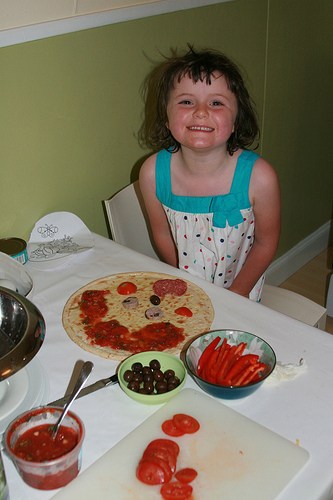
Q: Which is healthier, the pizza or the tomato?
A: The tomato is healthier than the pizza.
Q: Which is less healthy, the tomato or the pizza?
A: The pizza is less healthy than the tomato.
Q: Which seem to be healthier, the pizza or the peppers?
A: The peppers are healthier than the pizza.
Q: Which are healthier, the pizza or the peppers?
A: The peppers are healthier than the pizza.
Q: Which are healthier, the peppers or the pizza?
A: The peppers are healthier than the pizza.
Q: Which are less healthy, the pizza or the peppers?
A: The pizza are less healthy than the peppers.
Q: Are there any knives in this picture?
A: Yes, there is a knife.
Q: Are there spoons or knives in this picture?
A: Yes, there is a knife.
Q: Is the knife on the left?
A: Yes, the knife is on the left of the image.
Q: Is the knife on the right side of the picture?
A: No, the knife is on the left of the image.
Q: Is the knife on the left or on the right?
A: The knife is on the left of the image.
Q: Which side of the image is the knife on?
A: The knife is on the left of the image.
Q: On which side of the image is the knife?
A: The knife is on the left of the image.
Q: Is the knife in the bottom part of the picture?
A: Yes, the knife is in the bottom of the image.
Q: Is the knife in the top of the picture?
A: No, the knife is in the bottom of the image.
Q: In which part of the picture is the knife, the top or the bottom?
A: The knife is in the bottom of the image.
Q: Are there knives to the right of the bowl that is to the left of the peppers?
A: No, the knife is to the left of the bowl.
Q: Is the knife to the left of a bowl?
A: Yes, the knife is to the left of a bowl.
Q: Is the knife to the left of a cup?
A: No, the knife is to the left of a bowl.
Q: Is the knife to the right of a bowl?
A: No, the knife is to the left of a bowl.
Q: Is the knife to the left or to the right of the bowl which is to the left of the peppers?
A: The knife is to the left of the bowl.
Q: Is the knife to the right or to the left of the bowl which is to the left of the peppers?
A: The knife is to the left of the bowl.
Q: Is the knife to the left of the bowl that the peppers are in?
A: Yes, the knife is to the left of the bowl.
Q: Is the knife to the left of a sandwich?
A: No, the knife is to the left of the bowl.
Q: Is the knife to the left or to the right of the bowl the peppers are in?
A: The knife is to the left of the bowl.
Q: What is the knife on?
A: The knife is on the table.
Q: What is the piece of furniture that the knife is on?
A: The piece of furniture is a table.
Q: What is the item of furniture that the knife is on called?
A: The piece of furniture is a table.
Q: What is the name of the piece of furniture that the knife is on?
A: The piece of furniture is a table.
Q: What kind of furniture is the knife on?
A: The knife is on the table.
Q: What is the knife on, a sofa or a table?
A: The knife is on a table.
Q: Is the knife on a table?
A: Yes, the knife is on a table.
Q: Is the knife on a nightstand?
A: No, the knife is on a table.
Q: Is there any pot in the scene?
A: No, there are no pots.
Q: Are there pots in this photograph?
A: No, there are no pots.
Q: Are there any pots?
A: No, there are no pots.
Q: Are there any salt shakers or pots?
A: No, there are no pots or salt shakers.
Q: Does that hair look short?
A: Yes, the hair is short.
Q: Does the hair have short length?
A: Yes, the hair is short.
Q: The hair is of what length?
A: The hair is short.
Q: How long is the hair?
A: The hair is short.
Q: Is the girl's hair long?
A: No, the hair is short.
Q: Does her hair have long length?
A: No, the hair is short.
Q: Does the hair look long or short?
A: The hair is short.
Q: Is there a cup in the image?
A: No, there are no cups.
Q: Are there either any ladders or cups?
A: No, there are no cups or ladders.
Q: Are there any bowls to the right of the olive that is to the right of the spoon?
A: Yes, there is a bowl to the right of the olive.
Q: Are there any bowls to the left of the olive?
A: No, the bowl is to the right of the olive.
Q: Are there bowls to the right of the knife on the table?
A: Yes, there is a bowl to the right of the knife.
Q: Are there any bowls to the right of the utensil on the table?
A: Yes, there is a bowl to the right of the knife.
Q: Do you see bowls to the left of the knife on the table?
A: No, the bowl is to the right of the knife.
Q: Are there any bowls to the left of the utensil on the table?
A: No, the bowl is to the right of the knife.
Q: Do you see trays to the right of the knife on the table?
A: No, there is a bowl to the right of the knife.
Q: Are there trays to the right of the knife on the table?
A: No, there is a bowl to the right of the knife.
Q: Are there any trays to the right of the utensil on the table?
A: No, there is a bowl to the right of the knife.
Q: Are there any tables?
A: Yes, there is a table.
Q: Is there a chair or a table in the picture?
A: Yes, there is a table.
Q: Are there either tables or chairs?
A: Yes, there is a table.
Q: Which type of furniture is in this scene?
A: The furniture is a table.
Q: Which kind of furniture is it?
A: The piece of furniture is a table.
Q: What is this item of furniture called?
A: That is a table.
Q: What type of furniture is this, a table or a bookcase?
A: That is a table.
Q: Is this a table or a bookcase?
A: This is a table.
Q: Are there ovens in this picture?
A: No, there are no ovens.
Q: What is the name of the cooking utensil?
A: The cooking utensil is a cutting board.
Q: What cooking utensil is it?
A: The cooking utensil is a cutting board.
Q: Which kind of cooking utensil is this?
A: That is a cutting board.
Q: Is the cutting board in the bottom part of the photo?
A: Yes, the cutting board is in the bottom of the image.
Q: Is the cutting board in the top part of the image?
A: No, the cutting board is in the bottom of the image.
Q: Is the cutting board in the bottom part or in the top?
A: The cutting board is in the bottom of the image.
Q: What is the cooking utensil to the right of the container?
A: The cooking utensil is a cutting board.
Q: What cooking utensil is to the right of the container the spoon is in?
A: The cooking utensil is a cutting board.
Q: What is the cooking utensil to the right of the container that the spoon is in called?
A: The cooking utensil is a cutting board.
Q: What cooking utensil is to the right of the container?
A: The cooking utensil is a cutting board.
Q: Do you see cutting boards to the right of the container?
A: Yes, there is a cutting board to the right of the container.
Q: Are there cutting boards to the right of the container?
A: Yes, there is a cutting board to the right of the container.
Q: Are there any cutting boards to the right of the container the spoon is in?
A: Yes, there is a cutting board to the right of the container.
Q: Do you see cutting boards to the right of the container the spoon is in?
A: Yes, there is a cutting board to the right of the container.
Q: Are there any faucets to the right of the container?
A: No, there is a cutting board to the right of the container.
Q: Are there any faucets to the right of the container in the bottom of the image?
A: No, there is a cutting board to the right of the container.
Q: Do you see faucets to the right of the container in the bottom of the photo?
A: No, there is a cutting board to the right of the container.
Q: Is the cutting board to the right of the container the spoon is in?
A: Yes, the cutting board is to the right of the container.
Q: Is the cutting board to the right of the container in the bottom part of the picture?
A: Yes, the cutting board is to the right of the container.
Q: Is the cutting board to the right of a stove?
A: No, the cutting board is to the right of the container.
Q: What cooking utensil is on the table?
A: The cooking utensil is a cutting board.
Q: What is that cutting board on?
A: The cutting board is on the table.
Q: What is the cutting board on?
A: The cutting board is on the table.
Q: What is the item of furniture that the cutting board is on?
A: The piece of furniture is a table.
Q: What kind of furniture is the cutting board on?
A: The cutting board is on the table.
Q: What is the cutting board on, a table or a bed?
A: The cutting board is on a table.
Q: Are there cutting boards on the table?
A: Yes, there is a cutting board on the table.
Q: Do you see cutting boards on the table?
A: Yes, there is a cutting board on the table.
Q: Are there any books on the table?
A: No, there is a cutting board on the table.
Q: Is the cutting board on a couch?
A: No, the cutting board is on the table.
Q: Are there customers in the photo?
A: No, there are no customers.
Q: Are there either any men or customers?
A: No, there are no customers or men.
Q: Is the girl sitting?
A: Yes, the girl is sitting.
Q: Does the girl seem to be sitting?
A: Yes, the girl is sitting.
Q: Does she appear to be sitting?
A: Yes, the girl is sitting.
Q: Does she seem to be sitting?
A: Yes, the girl is sitting.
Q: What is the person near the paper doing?
A: The girl is sitting.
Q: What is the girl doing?
A: The girl is sitting.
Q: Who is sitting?
A: The girl is sitting.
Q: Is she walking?
A: No, the girl is sitting.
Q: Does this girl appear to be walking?
A: No, the girl is sitting.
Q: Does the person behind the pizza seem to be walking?
A: No, the girl is sitting.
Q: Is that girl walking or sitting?
A: The girl is sitting.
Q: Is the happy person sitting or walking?
A: The girl is sitting.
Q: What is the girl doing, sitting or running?
A: The girl is sitting.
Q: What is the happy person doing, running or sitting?
A: The girl is sitting.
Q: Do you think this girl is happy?
A: Yes, the girl is happy.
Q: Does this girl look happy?
A: Yes, the girl is happy.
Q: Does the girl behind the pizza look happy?
A: Yes, the girl is happy.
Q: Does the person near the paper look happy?
A: Yes, the girl is happy.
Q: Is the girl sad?
A: No, the girl is happy.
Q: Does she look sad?
A: No, the girl is happy.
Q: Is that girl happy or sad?
A: The girl is happy.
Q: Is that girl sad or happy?
A: The girl is happy.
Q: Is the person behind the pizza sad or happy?
A: The girl is happy.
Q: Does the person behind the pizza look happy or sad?
A: The girl is happy.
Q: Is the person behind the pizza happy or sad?
A: The girl is happy.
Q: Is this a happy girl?
A: Yes, this is a happy girl.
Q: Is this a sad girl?
A: No, this is a happy girl.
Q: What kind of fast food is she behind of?
A: The girl is behind the pizza.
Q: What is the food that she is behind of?
A: The food is a pizza.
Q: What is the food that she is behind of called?
A: The food is a pizza.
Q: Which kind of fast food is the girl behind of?
A: The girl is behind the pizza.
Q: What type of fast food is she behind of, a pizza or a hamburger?
A: The girl is behind a pizza.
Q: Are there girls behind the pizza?
A: Yes, there is a girl behind the pizza.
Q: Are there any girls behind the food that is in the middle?
A: Yes, there is a girl behind the pizza.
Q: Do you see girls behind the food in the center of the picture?
A: Yes, there is a girl behind the pizza.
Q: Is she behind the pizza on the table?
A: Yes, the girl is behind the pizza.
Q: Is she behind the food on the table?
A: Yes, the girl is behind the pizza.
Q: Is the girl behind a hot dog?
A: No, the girl is behind the pizza.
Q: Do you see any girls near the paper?
A: Yes, there is a girl near the paper.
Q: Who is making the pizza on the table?
A: The girl is making the pizza.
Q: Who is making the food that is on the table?
A: The girl is making the pizza.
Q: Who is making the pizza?
A: The girl is making the pizza.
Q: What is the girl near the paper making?
A: The girl is making the pizza.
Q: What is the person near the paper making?
A: The girl is making the pizza.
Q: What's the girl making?
A: The girl is making the pizza.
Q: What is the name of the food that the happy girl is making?
A: The food is a pizza.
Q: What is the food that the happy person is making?
A: The food is a pizza.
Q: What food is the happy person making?
A: The girl is making the pizza.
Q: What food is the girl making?
A: The girl is making the pizza.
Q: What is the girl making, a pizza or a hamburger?
A: The girl is making a pizza.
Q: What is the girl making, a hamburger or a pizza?
A: The girl is making a pizza.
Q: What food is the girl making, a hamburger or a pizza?
A: The girl is making a pizza.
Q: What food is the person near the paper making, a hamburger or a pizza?
A: The girl is making a pizza.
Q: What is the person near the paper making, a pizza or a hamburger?
A: The girl is making a pizza.